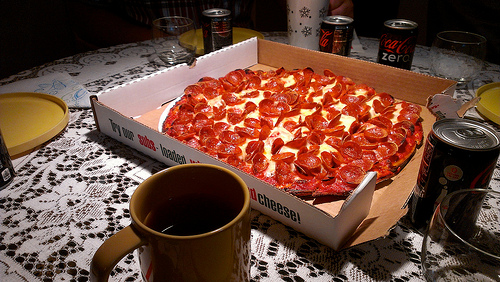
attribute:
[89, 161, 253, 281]
mug — brown, yellow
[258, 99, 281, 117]
pepperoni — redd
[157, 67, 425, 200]
pizza — large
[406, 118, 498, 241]
can — metal, beverage, unopened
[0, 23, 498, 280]
table — lace, white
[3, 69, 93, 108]
napkin — paper, folden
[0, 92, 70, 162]
plate — yellow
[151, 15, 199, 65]
glass — clear, full, empty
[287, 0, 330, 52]
cup — plastic, white